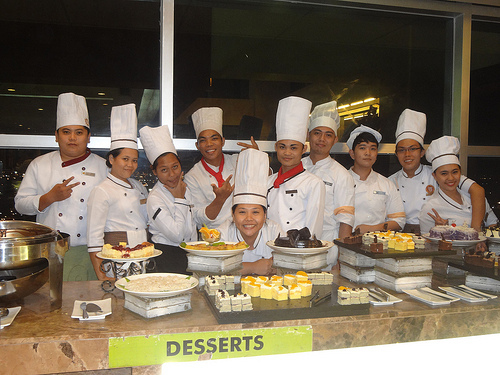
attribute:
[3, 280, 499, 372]
counter — brownish, marble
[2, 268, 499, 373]
table — marble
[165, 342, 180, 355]
letter — black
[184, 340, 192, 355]
letter — black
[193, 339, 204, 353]
letter — black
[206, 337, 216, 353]
letter — black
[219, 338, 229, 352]
letter — black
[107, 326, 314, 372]
sign — yellow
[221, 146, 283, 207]
hat — white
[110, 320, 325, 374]
sign — green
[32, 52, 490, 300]
group — posing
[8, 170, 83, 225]
arm — folded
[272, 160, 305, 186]
fabric — red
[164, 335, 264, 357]
letters — black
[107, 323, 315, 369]
sign — green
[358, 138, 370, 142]
hair — black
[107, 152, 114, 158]
hair — black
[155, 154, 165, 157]
hair — black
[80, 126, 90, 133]
hair — black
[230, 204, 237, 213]
hair — black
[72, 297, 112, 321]
napkin — white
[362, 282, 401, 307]
napkin — white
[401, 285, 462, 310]
napkin — white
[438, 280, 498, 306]
napkin — white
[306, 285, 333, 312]
tongs — silver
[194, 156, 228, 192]
tie — red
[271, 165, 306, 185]
scarf — red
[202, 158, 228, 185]
scarf — red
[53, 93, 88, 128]
chef hat — white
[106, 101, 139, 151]
chef hat — white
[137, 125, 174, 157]
chef hat — white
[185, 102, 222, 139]
chef hat — white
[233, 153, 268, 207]
chef hat — white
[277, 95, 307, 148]
chef hat — white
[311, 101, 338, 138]
chef hat — white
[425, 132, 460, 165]
chef hat — white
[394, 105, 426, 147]
chef hat — white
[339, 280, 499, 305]
napkins — white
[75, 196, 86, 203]
button — black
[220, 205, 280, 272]
person — asian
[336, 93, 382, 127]
lights — bright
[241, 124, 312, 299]
women — smiling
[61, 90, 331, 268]
women — posing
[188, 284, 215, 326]
counter — marble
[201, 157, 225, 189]
scarf — red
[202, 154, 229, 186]
scarf — red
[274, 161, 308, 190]
scarf — red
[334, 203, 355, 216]
stripe — beige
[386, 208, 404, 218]
stripe — beige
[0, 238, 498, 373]
table — brown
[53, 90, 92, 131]
hat — white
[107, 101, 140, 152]
hat — white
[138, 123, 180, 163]
hat — white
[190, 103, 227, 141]
hat — white